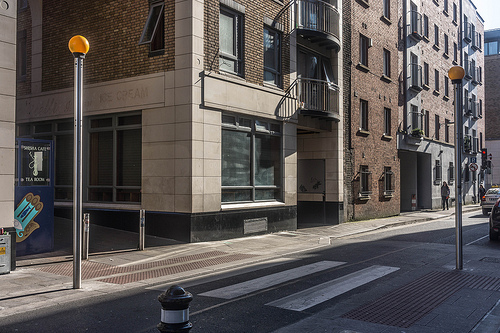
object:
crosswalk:
[135, 256, 446, 316]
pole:
[73, 57, 82, 289]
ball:
[66, 35, 92, 57]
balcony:
[298, 0, 342, 59]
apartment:
[19, 0, 484, 243]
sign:
[17, 71, 165, 123]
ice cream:
[98, 86, 148, 103]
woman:
[440, 180, 450, 212]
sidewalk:
[0, 202, 483, 317]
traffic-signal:
[482, 150, 486, 154]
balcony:
[296, 76, 340, 121]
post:
[453, 82, 464, 270]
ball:
[449, 67, 465, 80]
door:
[17, 137, 54, 256]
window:
[222, 128, 253, 204]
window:
[254, 132, 282, 201]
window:
[139, 2, 164, 52]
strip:
[93, 253, 259, 285]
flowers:
[422, 131, 426, 135]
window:
[411, 103, 418, 132]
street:
[2, 194, 500, 333]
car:
[482, 187, 499, 214]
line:
[197, 258, 347, 301]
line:
[265, 264, 401, 312]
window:
[264, 26, 280, 87]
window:
[219, 9, 242, 74]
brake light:
[481, 195, 486, 201]